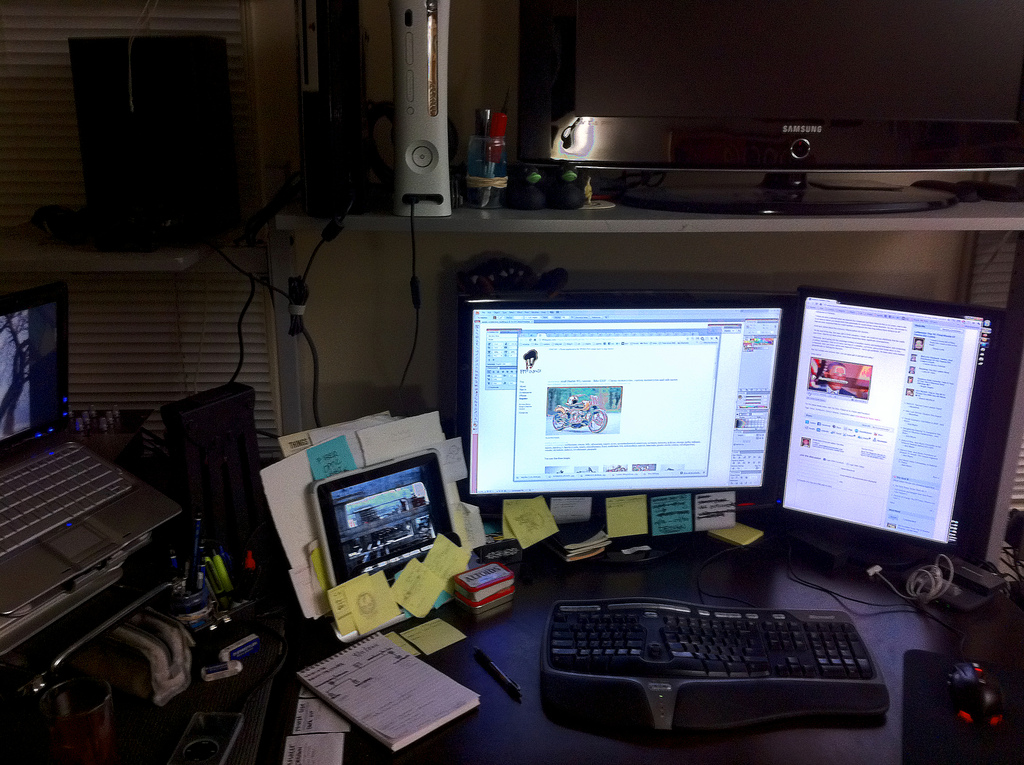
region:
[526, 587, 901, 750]
a computer keyboard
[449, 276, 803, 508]
a computer monitor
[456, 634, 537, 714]
a pen laying by the keyboard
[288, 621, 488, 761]
a spiral bound note pad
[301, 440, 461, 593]
an electronic tablet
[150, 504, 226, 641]
a cup with pens in it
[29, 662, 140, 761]
a coffee mug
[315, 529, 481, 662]
group of yellow post it notes on electronic tablet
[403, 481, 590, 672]
The man is sitting down using a laptop.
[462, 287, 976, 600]
a computer with dual monitors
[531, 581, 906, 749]
a black computer keyboard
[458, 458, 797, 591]
sticky notes on a computer monitor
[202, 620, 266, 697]
a couple of white erasers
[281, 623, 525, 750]
a notepad with a pen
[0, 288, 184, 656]
a laptop computer with lights on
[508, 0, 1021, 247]
a Samsung LCD television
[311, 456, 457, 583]
a flat screen tablet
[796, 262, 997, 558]
a flat screen monitor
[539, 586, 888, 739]
a black ergonomic keyboard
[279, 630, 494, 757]
a white note pad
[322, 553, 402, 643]
yellow post it notes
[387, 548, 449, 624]
yellow post it note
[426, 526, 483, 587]
yellow post it note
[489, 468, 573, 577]
yellow post it note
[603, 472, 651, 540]
yellow post it note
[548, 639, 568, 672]
a key on a keyboard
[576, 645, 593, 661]
a key on a keyboard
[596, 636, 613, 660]
a key on a keyboard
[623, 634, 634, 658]
a key on a keyboard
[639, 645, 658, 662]
a key on a keyboard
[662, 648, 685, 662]
a key on a keyboard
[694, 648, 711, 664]
a key on a keyboard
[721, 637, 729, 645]
a key on a keyboard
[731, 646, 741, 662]
a key on a keyboard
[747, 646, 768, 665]
a key on a keyboard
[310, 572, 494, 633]
Post it on the monitor.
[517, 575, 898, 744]
A keyboard on the table.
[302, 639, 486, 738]
A notepad on the table.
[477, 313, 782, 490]
The monitor screen is on.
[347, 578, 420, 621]
The sticky is yellow.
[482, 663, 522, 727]
A pen on the table.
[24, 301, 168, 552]
A laptop in the corner.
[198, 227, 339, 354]
Black cords hanging from the shelf.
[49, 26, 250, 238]
A black speaker on the shelf.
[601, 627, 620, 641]
A key on a keyboard.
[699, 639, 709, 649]
A key on a keyboard.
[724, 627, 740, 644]
A key on a keyboard.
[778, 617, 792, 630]
A key on a keyboard.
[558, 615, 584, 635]
A key on a keyboard.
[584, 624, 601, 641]
A key on a keyboard.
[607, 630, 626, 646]
A key on a keyboard.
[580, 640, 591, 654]
A key on a keyboard.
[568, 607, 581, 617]
a key on a keyboard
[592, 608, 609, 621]
a key on a keyboard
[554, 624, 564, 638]
a key on a keyboard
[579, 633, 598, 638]
a key on a keyboard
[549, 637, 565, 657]
a key on a keyboard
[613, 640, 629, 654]
a key on a keyboard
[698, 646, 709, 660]
a key on a keyboard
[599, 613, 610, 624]
keyboard has a black key